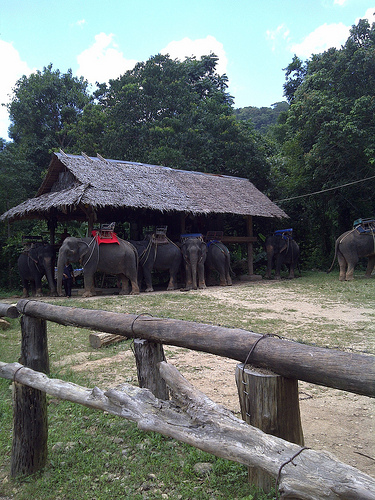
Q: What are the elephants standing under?
A: Shaded area.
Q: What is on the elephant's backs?
A: Seats.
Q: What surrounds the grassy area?
A: Fence.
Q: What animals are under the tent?
A: Elephants.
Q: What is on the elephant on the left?
A: A red blanket and seat.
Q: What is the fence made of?
A: Logs and tree stumps.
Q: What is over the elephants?
A: A thatched roof.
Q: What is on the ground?
A: Grass and dirt.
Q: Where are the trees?
A: Behind the elephants.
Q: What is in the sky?
A: Some clouds.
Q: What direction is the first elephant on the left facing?
A: Left.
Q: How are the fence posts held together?
A: Wire.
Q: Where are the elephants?
A: In the shade.